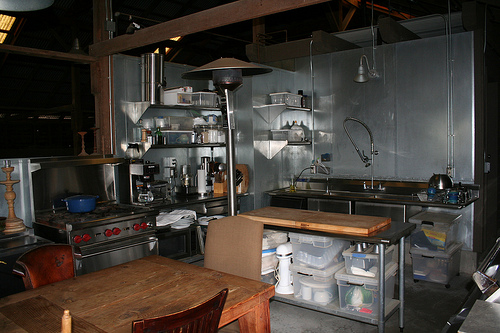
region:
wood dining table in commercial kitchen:
[4, 249, 269, 331]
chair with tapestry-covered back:
[202, 213, 262, 283]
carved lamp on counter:
[0, 158, 26, 238]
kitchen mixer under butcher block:
[271, 236, 299, 301]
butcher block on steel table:
[234, 198, 391, 236]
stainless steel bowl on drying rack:
[426, 170, 454, 193]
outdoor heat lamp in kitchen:
[186, 51, 271, 220]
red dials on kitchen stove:
[70, 220, 150, 246]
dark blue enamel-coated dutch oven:
[62, 191, 97, 215]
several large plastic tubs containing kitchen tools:
[287, 230, 398, 317]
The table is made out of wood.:
[0, 240, 272, 328]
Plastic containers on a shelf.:
[250, 221, 391, 317]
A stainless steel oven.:
[50, 168, 161, 270]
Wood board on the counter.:
[227, 198, 397, 246]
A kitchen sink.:
[302, 172, 412, 202]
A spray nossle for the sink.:
[325, 110, 385, 167]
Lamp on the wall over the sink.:
[346, 50, 381, 90]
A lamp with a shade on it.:
[170, 46, 280, 108]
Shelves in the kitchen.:
[126, 73, 228, 199]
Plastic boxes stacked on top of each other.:
[403, 216, 468, 295]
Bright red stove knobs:
[63, 220, 163, 247]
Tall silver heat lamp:
[181, 47, 281, 225]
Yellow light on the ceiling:
[0, 10, 20, 55]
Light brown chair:
[188, 200, 270, 283]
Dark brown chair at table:
[10, 238, 82, 290]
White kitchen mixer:
[270, 237, 298, 298]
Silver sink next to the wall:
[286, 112, 416, 212]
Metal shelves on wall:
[252, 89, 310, 153]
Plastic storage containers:
[288, 230, 387, 321]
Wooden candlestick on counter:
[74, 122, 92, 159]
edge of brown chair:
[169, 289, 276, 319]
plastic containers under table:
[279, 227, 329, 302]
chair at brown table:
[14, 230, 106, 293]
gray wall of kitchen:
[394, 94, 474, 173]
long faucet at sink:
[324, 105, 394, 180]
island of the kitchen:
[250, 191, 391, 253]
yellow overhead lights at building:
[0, 13, 25, 45]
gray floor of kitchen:
[268, 296, 343, 329]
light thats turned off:
[341, 55, 386, 106]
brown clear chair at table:
[201, 215, 288, 275]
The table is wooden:
[77, 273, 200, 329]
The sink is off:
[328, 98, 413, 214]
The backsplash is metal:
[363, 70, 457, 187]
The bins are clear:
[283, 218, 393, 331]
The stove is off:
[56, 185, 144, 275]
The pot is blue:
[53, 186, 128, 241]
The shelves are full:
[152, 87, 254, 194]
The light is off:
[334, 45, 425, 101]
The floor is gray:
[278, 304, 320, 324]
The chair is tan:
[183, 195, 286, 304]